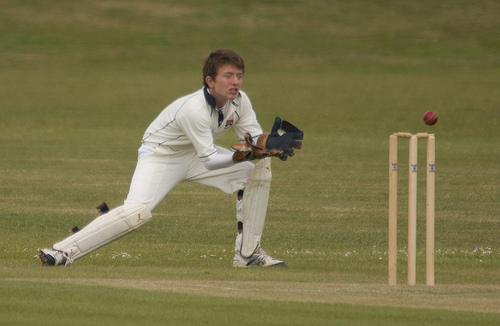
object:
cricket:
[388, 131, 437, 286]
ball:
[423, 110, 438, 126]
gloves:
[232, 132, 285, 163]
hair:
[202, 51, 244, 88]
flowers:
[103, 246, 149, 263]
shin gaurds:
[53, 158, 273, 257]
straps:
[232, 190, 246, 237]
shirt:
[137, 90, 262, 161]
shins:
[51, 204, 150, 252]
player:
[39, 48, 304, 269]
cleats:
[232, 250, 286, 268]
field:
[2, 3, 499, 325]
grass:
[0, 1, 499, 324]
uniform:
[56, 89, 274, 249]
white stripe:
[428, 113, 435, 123]